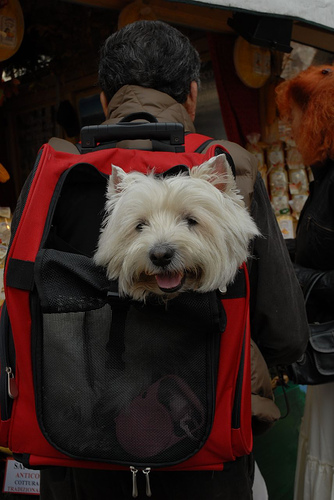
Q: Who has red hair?
A: The woman on the right.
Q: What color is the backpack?
A: Red.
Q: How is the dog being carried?
A: In a backpack.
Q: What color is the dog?
A: White.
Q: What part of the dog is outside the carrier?
A: Head.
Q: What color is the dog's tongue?
A: Pink.